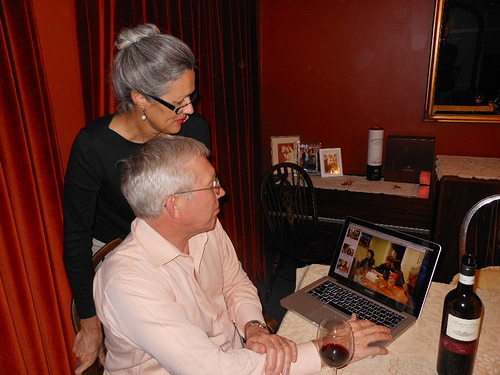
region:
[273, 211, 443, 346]
Laptop on a table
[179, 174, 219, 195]
Glasses on a man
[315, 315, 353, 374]
Wine glass on a table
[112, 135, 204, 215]
Gray hair on a man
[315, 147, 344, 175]
White framed picture on a shelf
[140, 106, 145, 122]
White round earring on a woman's ear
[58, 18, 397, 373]
two elderly people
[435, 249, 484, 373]
an open bottle of wine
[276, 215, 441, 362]
a silver laptop that is on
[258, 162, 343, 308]
a dark brown wood chair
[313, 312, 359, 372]
glass of red wine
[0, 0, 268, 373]
long thick curtains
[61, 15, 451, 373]
two people looking at a laptop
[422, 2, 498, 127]
a gold framed mirror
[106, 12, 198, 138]
a woman wearing a bun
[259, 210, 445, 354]
a gray laptop turned on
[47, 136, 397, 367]
an elderly man sitting down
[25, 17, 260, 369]
an elderly woman standing up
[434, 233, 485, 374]
a bottle of wine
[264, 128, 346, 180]
three pictures on a table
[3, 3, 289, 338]
a red curtain hanging on a wall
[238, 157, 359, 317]
a dark brown chair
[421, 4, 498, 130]
a mirror with a gold frame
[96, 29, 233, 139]
head of a lady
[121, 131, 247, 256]
head of a man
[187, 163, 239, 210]
glasses on the man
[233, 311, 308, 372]
hand of the man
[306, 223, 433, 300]
screen of the laptop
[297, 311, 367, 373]
glass with liquid inside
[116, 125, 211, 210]
gray hair on man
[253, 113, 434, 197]
items on the stand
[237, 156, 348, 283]
chair next to lady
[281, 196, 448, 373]
Laptop showing pictures on it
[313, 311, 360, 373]
Glass of wine on the table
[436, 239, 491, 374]
Bottle of wine on the table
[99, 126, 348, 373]
Man in glasses looking at the pictures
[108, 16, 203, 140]
Woman has gray hair in a bun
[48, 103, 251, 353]
Woman wearing a black top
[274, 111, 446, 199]
Pictures seen on the counter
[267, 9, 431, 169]
Wall painted in a dark color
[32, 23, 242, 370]
Woman standing behind the man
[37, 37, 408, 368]
these are two people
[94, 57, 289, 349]
the people are elderly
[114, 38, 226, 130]
the lady has grey hair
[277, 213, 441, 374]
open silver laptop near glass of wine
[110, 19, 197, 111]
grey hair pulled back in a bun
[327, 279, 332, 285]
laptop has a black key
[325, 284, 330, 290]
laptop has a black key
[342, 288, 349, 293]
laptop has a black key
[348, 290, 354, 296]
laptop has a black key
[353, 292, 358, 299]
laptop has a black key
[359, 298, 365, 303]
laptop has a black key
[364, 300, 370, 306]
laptop has a black key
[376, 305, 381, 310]
laptop has a black key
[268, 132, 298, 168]
nick knack on the wooden cabinet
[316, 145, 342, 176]
nick knack on the wooden cabinet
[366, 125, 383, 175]
nick knack on the wooden cabinet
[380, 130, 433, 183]
nick knack on the wooden cabinet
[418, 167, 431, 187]
nick knack on the wooden cabinet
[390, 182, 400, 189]
nick knack on the wooden cabinet